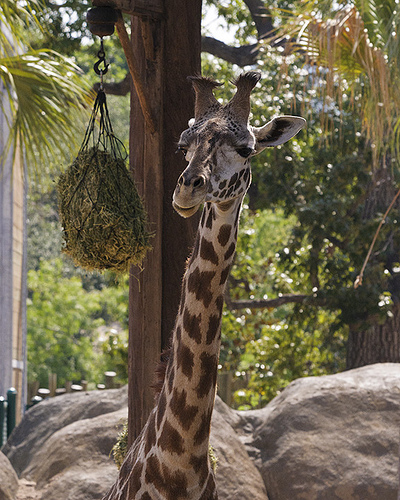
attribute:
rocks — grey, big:
[1, 360, 400, 497]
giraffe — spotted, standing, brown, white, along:
[104, 73, 307, 499]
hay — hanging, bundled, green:
[56, 147, 154, 278]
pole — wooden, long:
[97, 0, 204, 460]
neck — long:
[147, 195, 257, 459]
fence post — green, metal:
[6, 387, 18, 432]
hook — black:
[91, 49, 113, 77]